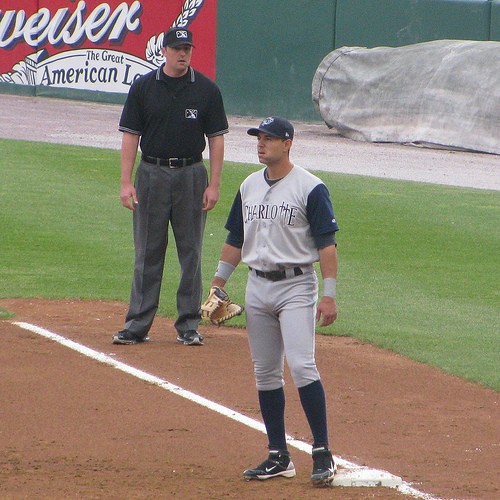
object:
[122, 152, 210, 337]
khakis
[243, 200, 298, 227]
lettering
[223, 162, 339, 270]
jersey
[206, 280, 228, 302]
hand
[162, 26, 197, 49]
cap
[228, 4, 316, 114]
wall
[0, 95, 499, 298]
outfield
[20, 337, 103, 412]
tan dirt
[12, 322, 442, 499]
white stripe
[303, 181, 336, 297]
arm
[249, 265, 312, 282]
belt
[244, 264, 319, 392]
pants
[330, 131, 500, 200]
ground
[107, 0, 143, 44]
white letter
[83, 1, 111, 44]
white letter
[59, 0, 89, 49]
white letter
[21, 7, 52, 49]
white letter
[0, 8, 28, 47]
white letter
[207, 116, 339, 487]
man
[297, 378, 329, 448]
socks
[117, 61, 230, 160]
shirt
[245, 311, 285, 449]
leg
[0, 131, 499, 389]
grass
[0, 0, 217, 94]
advertisement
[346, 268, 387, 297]
leaves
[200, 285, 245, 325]
baseball glove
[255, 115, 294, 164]
head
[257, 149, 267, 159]
mouth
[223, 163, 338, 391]
uniform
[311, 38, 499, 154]
canvas sleeve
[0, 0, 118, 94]
wall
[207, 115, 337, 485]
baseball player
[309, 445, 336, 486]
foot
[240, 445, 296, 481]
foot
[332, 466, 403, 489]
plate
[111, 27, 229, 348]
man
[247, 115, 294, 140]
cap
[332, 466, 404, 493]
base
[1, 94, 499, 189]
warning track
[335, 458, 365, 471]
dirt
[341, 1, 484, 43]
wall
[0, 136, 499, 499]
field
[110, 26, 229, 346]
umpire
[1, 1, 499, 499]
baseball field